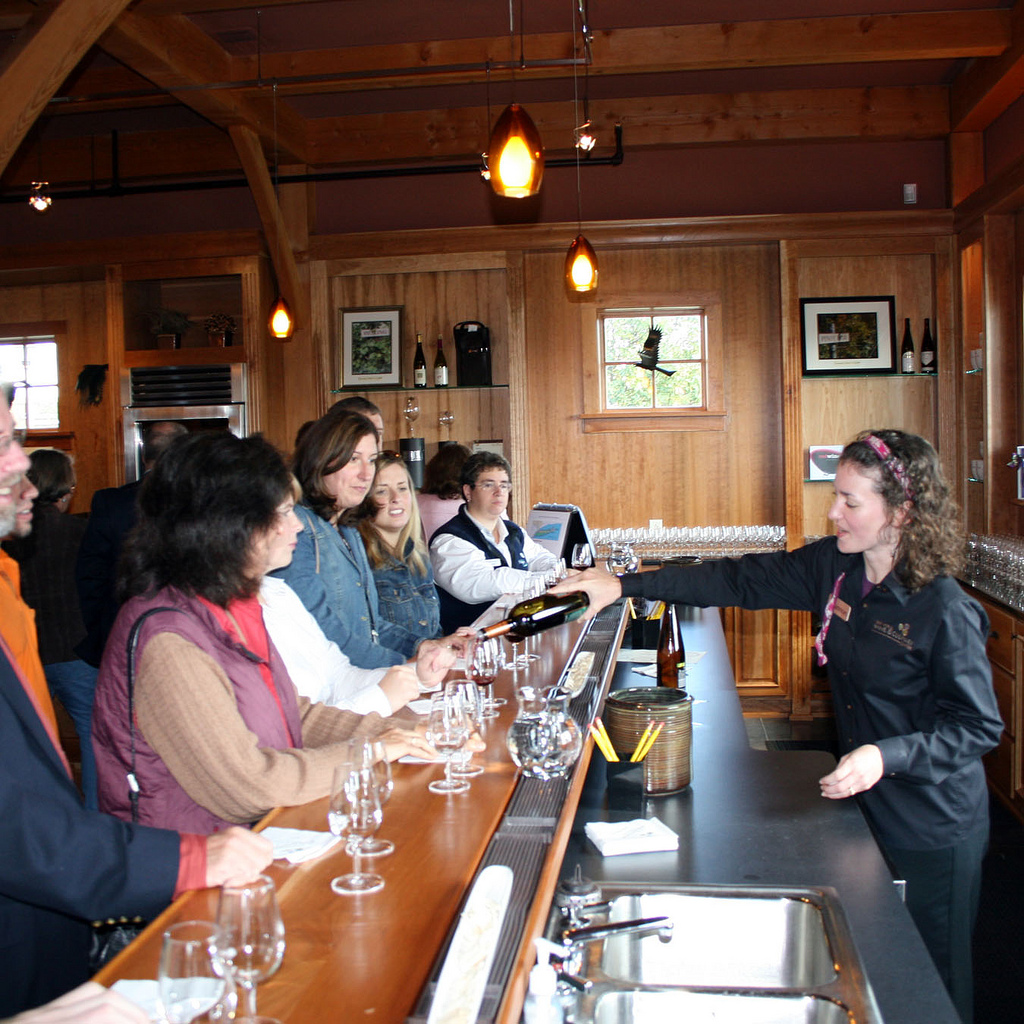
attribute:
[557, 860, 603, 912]
drain — on the sink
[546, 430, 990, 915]
woman — pouring the wine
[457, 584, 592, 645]
wine bottle — being poured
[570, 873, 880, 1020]
basin sink — double, in the counter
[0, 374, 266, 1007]
person — wearing orange shirt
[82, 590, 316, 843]
vest — pink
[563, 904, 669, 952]
faucet — silver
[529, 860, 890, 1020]
sink — silver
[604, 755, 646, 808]
cup — black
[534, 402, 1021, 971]
bartender — woman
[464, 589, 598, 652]
bottle — green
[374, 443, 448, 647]
woman — blonde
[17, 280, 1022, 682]
walls — wood paneled